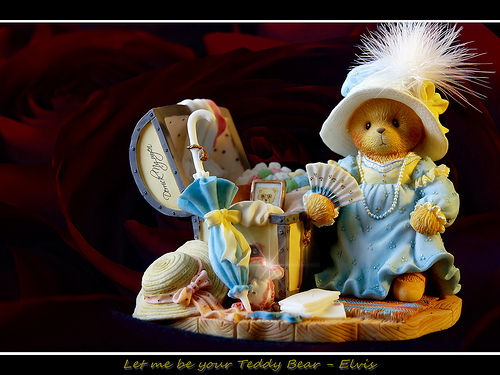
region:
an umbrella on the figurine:
[173, 108, 286, 325]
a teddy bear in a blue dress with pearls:
[326, 56, 480, 300]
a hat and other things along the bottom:
[121, 236, 303, 369]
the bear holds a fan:
[291, 148, 368, 243]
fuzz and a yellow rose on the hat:
[353, 39, 485, 126]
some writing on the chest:
[140, 126, 190, 224]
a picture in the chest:
[238, 161, 312, 233]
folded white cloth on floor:
[269, 269, 351, 329]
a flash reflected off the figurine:
[241, 235, 285, 280]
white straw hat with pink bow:
[120, 235, 225, 325]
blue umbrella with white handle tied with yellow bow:
[181, 103, 251, 330]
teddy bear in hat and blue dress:
[297, 15, 483, 323]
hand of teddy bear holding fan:
[292, 159, 369, 229]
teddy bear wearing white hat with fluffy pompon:
[298, 22, 473, 159]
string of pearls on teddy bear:
[347, 150, 417, 228]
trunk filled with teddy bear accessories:
[104, 81, 323, 284]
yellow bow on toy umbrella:
[207, 206, 256, 268]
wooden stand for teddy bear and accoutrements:
[137, 259, 481, 341]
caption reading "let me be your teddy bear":
[117, 355, 378, 373]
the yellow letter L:
[116, 353, 136, 373]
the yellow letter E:
[129, 358, 140, 370]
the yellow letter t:
[135, 353, 153, 373]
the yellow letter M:
[148, 356, 165, 373]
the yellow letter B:
[173, 358, 189, 372]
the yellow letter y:
[196, 357, 208, 374]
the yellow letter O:
[203, 358, 215, 373]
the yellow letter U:
[211, 360, 227, 372]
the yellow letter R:
[223, 356, 234, 373]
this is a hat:
[108, 218, 258, 333]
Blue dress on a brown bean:
[335, 147, 462, 302]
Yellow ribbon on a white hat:
[402, 75, 452, 135]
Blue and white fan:
[305, 156, 361, 216]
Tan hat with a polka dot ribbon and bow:
[135, 245, 217, 320]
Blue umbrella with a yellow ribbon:
[185, 105, 250, 315]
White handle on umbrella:
[180, 106, 215, 181]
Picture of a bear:
[245, 176, 281, 206]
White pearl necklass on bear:
[352, 147, 412, 218]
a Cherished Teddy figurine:
[128, 22, 493, 342]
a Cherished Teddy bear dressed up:
[300, 22, 491, 299]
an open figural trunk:
[129, 103, 323, 302]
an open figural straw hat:
[133, 242, 224, 320]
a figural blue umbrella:
[177, 108, 254, 315]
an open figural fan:
[307, 161, 366, 206]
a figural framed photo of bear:
[249, 177, 285, 207]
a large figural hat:
[319, 23, 494, 161]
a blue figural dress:
[307, 151, 463, 298]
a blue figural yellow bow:
[422, 80, 448, 135]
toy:
[101, 43, 466, 344]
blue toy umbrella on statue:
[168, 162, 270, 289]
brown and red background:
[11, 65, 59, 106]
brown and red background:
[70, 273, 88, 298]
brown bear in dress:
[327, 28, 479, 298]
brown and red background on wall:
[42, 273, 70, 298]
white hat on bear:
[317, 35, 438, 124]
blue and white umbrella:
[155, 176, 281, 351]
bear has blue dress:
[317, 158, 452, 281]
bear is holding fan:
[290, 151, 375, 227]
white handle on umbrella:
[137, 90, 268, 212]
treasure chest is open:
[126, 106, 268, 200]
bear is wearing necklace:
[355, 127, 430, 239]